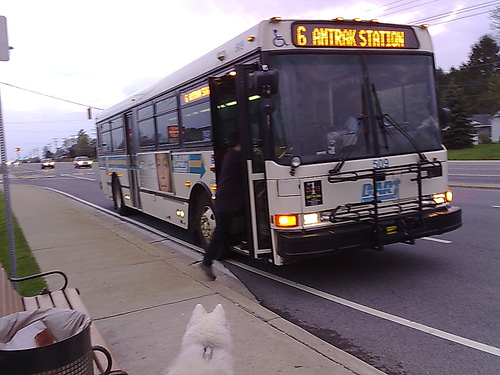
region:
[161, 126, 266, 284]
person getting in bus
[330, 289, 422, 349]
white line on ground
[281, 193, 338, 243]
light on front of bus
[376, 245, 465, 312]
street under the bus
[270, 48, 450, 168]
front window of bus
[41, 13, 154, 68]
sky above the street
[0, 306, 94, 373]
a trash can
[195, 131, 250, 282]
a person entering bus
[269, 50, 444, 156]
the wide windshield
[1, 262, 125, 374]
the wooden bench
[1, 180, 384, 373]
the paved sidewalk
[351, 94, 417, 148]
the bus driver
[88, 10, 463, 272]
a bus on the road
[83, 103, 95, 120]
the traffic light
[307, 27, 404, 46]
the words are golden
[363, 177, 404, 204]
the logo is blue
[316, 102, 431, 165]
the wipers are black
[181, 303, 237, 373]
the dog is white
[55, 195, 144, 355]
the sidewalk is paved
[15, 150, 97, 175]
the cars are moving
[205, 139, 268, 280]
person getting on the bus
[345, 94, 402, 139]
man driving the bus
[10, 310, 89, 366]
bag in the trash can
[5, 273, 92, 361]
the bench is brown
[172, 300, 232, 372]
The dog is facing the bus.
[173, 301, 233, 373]
The dog is white in color.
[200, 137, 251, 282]
The man is entering the bus.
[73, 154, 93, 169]
The car has its headlights on.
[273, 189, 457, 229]
The bus has its headlights on.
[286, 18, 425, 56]
The next stop for the bus is the Amtrack Station.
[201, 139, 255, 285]
The man is wearing black.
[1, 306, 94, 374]
The garbage can is next to the bench.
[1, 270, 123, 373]
The bench is brown in color.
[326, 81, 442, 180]
The windshield wipers are black.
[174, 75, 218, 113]
bright light on bus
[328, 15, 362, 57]
bright light on bus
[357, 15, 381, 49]
bright light on bus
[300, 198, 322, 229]
bright light on bus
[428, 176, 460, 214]
bright light on bus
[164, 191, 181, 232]
bright light on bus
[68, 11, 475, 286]
a bus parked on side a road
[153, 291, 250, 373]
a white dog on a sidewalk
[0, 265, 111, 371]
basket of clothes over a bench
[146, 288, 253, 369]
There's a white dog sitting on the sidewalk.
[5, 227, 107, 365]
There's a trash can next to this bench.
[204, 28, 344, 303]
A passenger is getting on the bus.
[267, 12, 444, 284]
This bus is going to the Amtrak Station.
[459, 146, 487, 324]
This is a four lane street.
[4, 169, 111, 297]
There's grass by the sidewalk.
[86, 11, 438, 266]
This is a bus.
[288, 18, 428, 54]
yellow letters on sign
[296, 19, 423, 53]
a sign on the bus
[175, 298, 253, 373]
a white dog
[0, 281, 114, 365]
the top of a trash can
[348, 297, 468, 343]
white line on road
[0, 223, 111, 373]
a wood bench by can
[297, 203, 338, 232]
a white lit head light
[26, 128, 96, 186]
cars behinde the bus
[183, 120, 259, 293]
a person getting on bus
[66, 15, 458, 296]
a bus on the side of road